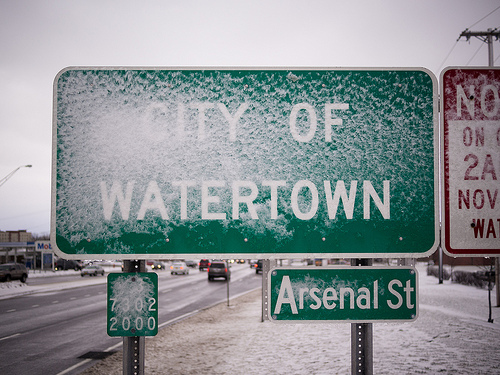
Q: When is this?
A: Daytime.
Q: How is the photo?
A: Clear.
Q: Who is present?
A: No one.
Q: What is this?
A: Sign.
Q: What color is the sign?
A: Green.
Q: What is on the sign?
A: Snow.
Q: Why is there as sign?
A: Notification.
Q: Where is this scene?
A: Entering city of Watertown.